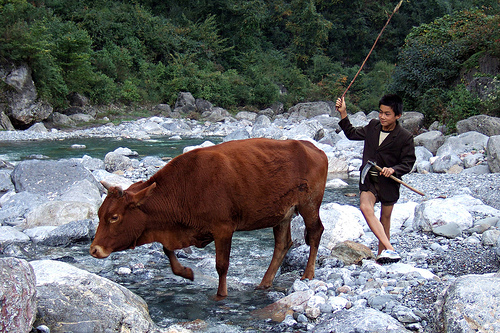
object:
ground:
[323, 156, 500, 333]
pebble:
[184, 317, 210, 331]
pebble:
[337, 285, 351, 293]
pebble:
[269, 307, 285, 324]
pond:
[1, 131, 226, 161]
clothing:
[378, 129, 391, 146]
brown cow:
[89, 138, 329, 301]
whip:
[334, 0, 404, 112]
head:
[88, 180, 146, 258]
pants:
[359, 182, 398, 206]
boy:
[335, 94, 416, 264]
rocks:
[439, 272, 500, 333]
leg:
[162, 248, 185, 276]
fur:
[187, 149, 314, 241]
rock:
[330, 240, 374, 264]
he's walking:
[299, 66, 454, 273]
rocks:
[311, 309, 411, 333]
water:
[0, 134, 362, 332]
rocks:
[37, 219, 98, 248]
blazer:
[338, 115, 416, 203]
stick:
[334, 1, 403, 113]